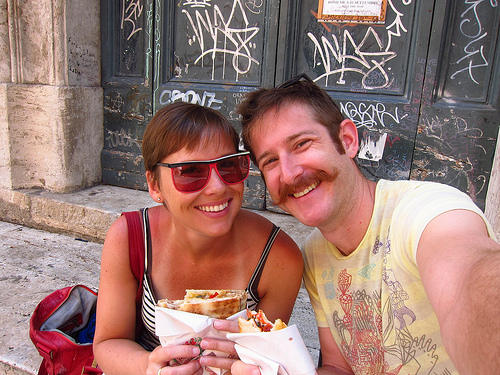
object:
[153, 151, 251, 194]
glasses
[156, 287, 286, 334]
food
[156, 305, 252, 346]
napkin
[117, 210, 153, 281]
strap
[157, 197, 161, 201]
earring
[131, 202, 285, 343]
white/black shirt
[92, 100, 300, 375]
woman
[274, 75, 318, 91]
pair sunglasses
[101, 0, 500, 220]
black wall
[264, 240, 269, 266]
string part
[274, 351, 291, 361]
paper part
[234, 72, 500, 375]
man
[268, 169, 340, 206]
mustache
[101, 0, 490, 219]
graffiti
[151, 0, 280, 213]
door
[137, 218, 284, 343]
tank top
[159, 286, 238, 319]
panini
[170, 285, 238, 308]
wrapper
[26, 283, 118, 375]
bag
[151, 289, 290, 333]
food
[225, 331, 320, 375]
paper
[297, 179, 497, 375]
shirt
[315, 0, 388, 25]
sign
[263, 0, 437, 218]
door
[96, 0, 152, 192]
doors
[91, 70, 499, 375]
couple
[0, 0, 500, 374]
picture